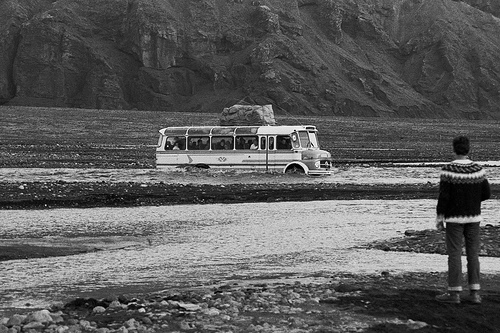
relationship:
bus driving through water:
[155, 118, 333, 179] [0, 160, 498, 187]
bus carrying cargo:
[155, 118, 333, 179] [218, 98, 277, 126]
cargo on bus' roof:
[218, 98, 277, 126] [155, 117, 313, 134]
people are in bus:
[166, 136, 291, 151] [155, 118, 333, 179]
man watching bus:
[433, 132, 493, 308] [155, 118, 333, 179]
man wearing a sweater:
[433, 132, 493, 308] [436, 159, 492, 225]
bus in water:
[155, 118, 333, 179] [0, 160, 498, 187]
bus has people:
[155, 118, 333, 179] [166, 136, 291, 151]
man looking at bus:
[433, 132, 493, 308] [155, 118, 333, 179]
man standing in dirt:
[433, 132, 493, 308] [332, 281, 497, 332]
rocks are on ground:
[11, 179, 232, 202] [1, 103, 500, 331]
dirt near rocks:
[0, 173, 496, 208] [11, 179, 232, 202]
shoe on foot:
[433, 286, 464, 307] [431, 286, 463, 307]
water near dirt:
[0, 160, 498, 187] [332, 281, 497, 332]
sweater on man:
[436, 159, 492, 225] [433, 132, 493, 308]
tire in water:
[283, 163, 305, 181] [0, 160, 498, 187]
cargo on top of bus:
[218, 98, 277, 126] [155, 118, 333, 179]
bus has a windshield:
[155, 118, 333, 179] [290, 129, 318, 150]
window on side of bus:
[234, 131, 260, 154] [155, 118, 333, 179]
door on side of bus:
[259, 132, 276, 170] [155, 118, 333, 179]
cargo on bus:
[218, 98, 277, 126] [155, 118, 333, 179]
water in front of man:
[0, 160, 498, 187] [433, 132, 493, 308]